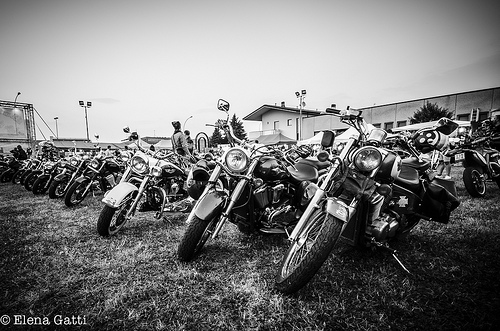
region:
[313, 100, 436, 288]
A motorcycle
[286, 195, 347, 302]
The wheel on a motorcycle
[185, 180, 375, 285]
The wheels on two motorcycles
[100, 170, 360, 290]
The wheels on three motorcycles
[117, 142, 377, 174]
The lights on three motorcycles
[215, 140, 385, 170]
The lights on two motorcycles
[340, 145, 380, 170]
The light on a motorcycle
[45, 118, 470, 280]
A bunch of motorcycles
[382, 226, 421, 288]
The kick stand on a motorcycle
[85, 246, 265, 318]
Grass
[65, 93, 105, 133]
Stadium light in the distance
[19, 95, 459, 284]
A group of motorcycles lined up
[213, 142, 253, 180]
Motorcycle headlight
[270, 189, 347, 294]
Front tire and fender of a motorcycle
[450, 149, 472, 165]
License plate on the back of motorcycle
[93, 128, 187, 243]
White fender and tire on front of motorcycle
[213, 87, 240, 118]
Right mirror on motorcycle handlebar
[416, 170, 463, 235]
Soft side saddle bags on motorcycle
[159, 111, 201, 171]
Two people standing by motorcycles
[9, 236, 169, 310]
Gray picture of grass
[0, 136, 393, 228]
Bikes are parked in line.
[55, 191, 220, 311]
Bikes are parked in grass.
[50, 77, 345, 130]
lights are attached to the pole.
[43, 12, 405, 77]
Sky is white color.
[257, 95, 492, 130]
Building is seen behind the bikes.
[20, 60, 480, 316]
Black and white picture.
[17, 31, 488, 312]
Day time picture.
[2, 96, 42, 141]
one advertisement board is seen.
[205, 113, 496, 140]
Trees are seen behind the bike.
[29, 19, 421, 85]
Sky is cloudy.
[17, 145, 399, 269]
motorcycles parked in grass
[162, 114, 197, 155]
two people standing among motorcycles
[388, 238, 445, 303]
motorcycle kick stand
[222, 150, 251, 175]
headlight on motorcycle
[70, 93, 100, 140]
light post with two lights on it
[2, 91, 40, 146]
billboard with light shinning on it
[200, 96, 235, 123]
side mirror on motorcycle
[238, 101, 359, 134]
white building with roof and overhang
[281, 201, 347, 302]
motorcycle tire in grass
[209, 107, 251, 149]
pine trees behind motorcycles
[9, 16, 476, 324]
Black and white photo.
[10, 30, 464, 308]
Exterior shot, daytime vista.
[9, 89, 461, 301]
Still life with landscape, vehicles and edifices.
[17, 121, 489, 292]
Many rows of parked motorcycles.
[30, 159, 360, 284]
Motorcycle tires, parked at a right slant.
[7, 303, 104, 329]
Lettering, showing photographer, and, or studio site.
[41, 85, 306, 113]
Tall lights back-dropping lot with bikes.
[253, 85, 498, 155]
Long, low building with mostly flat roof.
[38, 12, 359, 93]
Somber, overcast looking sky.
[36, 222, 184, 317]
Short, scruffy, dry-looking grass.